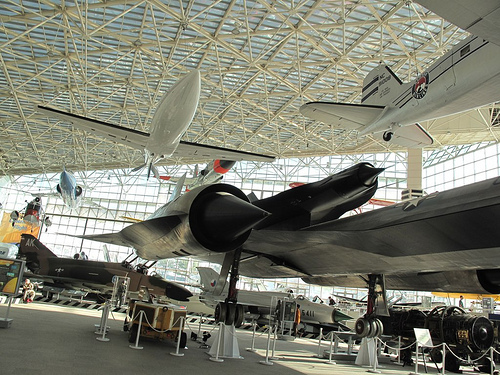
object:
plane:
[13, 231, 193, 304]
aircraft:
[9, 227, 197, 308]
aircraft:
[167, 265, 360, 325]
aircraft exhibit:
[2, 0, 499, 372]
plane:
[35, 68, 277, 182]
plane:
[298, 0, 500, 149]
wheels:
[353, 312, 384, 337]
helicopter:
[0, 192, 54, 246]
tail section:
[14, 232, 57, 279]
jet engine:
[93, 183, 258, 263]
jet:
[12, 231, 196, 306]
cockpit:
[114, 261, 156, 285]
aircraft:
[52, 158, 500, 342]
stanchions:
[168, 316, 192, 361]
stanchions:
[209, 322, 225, 362]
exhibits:
[56, 161, 498, 341]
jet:
[57, 159, 500, 339]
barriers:
[93, 299, 280, 367]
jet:
[33, 66, 279, 182]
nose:
[170, 63, 212, 98]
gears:
[211, 295, 248, 327]